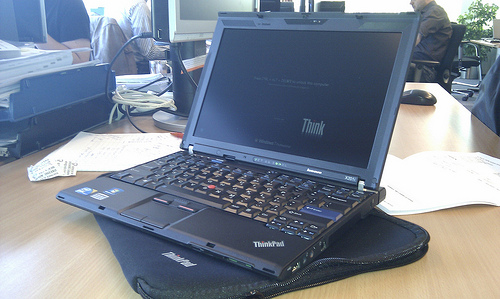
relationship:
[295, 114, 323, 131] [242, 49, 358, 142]
words on screen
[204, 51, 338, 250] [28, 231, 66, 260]
laptop on table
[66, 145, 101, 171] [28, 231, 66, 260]
paper on table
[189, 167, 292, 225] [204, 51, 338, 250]
keyboard of laptop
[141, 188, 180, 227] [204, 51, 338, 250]
trackpad of laptop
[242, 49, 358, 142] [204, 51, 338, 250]
screen on laptop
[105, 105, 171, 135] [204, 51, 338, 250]
cords behind laptop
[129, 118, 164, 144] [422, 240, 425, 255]
papers on desk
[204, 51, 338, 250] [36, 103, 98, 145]
laptop on bag